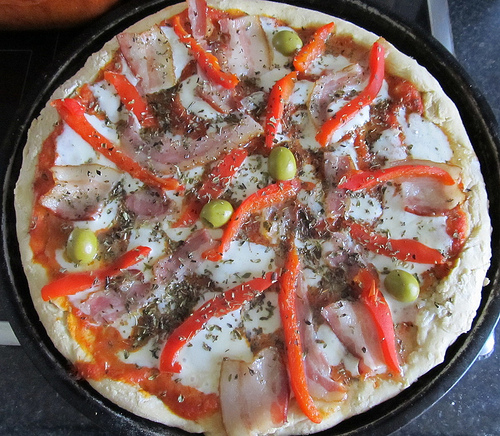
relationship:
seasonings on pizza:
[137, 221, 254, 291] [151, 129, 457, 377]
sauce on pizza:
[32, 221, 77, 249] [133, 146, 333, 319]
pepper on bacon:
[252, 299, 320, 379] [303, 329, 353, 400]